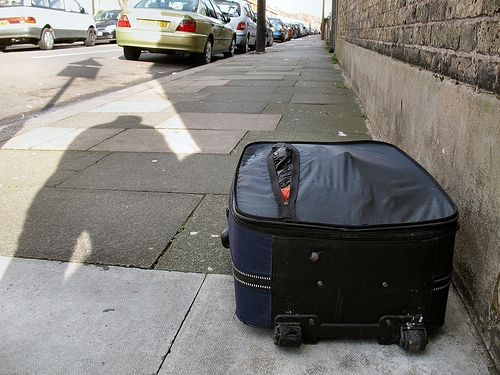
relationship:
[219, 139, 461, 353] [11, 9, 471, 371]
blue luggage sitting on sidewalk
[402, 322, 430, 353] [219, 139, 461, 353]
wheel mounted on blue luggage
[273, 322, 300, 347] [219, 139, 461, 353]
wheel mounted on blue luggage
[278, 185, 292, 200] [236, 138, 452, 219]
object lying in compartment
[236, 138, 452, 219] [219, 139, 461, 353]
compartment belonging to blue luggage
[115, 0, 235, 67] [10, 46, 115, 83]
car parked on street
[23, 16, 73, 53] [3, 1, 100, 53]
wheel on vehicle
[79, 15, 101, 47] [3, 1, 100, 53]
wheel on vehicle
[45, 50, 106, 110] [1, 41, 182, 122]
shadow on street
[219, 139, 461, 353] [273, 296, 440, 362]
blue luggage has wheels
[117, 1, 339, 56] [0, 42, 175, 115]
cars on side of street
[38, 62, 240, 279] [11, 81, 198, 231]
ground has shadows